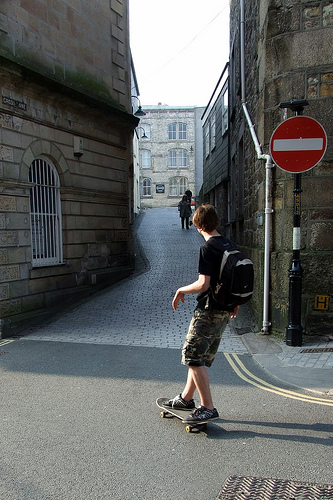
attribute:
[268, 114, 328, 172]
sign — Red, white , large, circular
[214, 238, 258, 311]
male — young 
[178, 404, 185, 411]
board — part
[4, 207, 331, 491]
road — part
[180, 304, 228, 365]
cargo pants — green, brown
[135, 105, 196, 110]
roof — green 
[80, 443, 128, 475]
black — H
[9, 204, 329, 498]
street — cobble stone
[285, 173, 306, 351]
post — part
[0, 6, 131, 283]
wall — part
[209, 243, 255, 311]
back pack — black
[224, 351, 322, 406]
lines — yellow, curved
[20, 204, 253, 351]
walk way — brick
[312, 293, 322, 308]
letter — yellow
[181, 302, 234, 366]
pants — green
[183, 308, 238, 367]
pattern — camo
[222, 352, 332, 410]
double lines — yellow